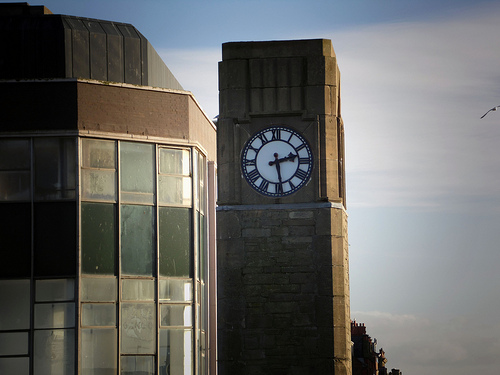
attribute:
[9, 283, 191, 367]
windows — big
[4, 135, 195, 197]
windows — big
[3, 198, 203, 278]
windows — big, green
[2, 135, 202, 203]
windows — big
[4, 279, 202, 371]
windows — big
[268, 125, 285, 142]
numeral — roman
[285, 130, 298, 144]
numeral — roman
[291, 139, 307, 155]
numeral — roman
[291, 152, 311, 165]
numeral — roman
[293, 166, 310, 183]
numeral — roman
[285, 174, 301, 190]
numeral — roman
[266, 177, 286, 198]
numeral — roman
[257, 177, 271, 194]
numeral — roman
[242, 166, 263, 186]
numeral — roman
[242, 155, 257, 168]
numeral — roman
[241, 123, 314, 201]
clockface — white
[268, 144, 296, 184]
dials — metal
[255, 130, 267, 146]
numerals — roman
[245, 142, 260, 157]
numerals — roman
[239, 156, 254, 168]
numerals — roman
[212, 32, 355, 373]
tower — concrete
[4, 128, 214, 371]
wall — windows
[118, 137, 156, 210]
window — glass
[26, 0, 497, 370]
sky — blue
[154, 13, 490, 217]
clouds — soft, greyish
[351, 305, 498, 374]
clouds — greyish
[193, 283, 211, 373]
windows — big, green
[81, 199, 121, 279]
windows — big, green